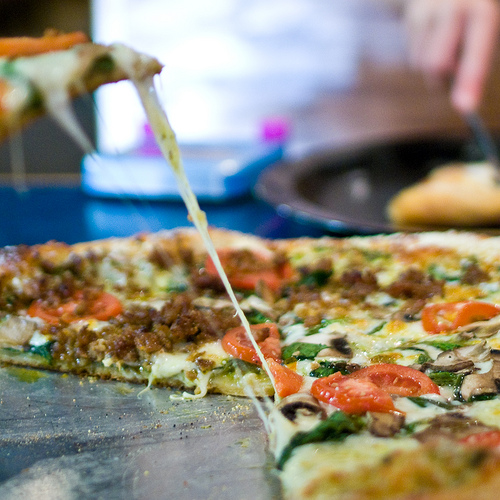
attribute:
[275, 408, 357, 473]
vegetable — green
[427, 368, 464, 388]
vegetable — green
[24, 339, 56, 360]
vegetable — green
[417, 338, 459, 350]
vegetable — green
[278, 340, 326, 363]
vegetable — green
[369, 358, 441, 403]
tomaoto — red, topping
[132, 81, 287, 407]
cheese — white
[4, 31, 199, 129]
pizza — sliced